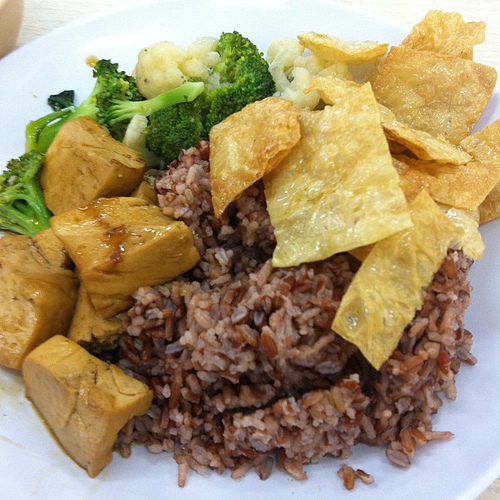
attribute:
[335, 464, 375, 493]
rice — brown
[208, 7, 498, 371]
food — crispy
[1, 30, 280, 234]
broccoli — green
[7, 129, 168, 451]
meat — white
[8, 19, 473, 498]
plate — white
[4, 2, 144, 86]
table — white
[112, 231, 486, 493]
rice — brown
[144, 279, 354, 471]
rice — brown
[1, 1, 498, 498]
dish — white, flat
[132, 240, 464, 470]
rice — brown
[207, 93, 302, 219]
chip — crispy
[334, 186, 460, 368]
chip — crispy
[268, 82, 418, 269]
chip — crispy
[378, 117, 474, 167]
chip — crispy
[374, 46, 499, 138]
chip — crispy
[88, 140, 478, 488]
rice — brown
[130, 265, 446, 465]
rice — brown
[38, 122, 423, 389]
tortillas — fried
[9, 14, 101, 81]
dish — white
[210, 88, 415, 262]
food — crispy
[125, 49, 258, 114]
food — white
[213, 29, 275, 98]
cauliflower — steamed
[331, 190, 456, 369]
tortilla chip — crisp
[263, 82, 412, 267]
tortilla chip — crisp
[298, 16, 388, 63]
tortilla chip — crisp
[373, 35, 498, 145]
tortilla chip — crisp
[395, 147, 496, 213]
tortilla chip — crisp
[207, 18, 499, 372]
chips — brown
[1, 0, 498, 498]
plate — white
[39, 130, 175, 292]
meat — square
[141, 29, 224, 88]
cauliflower — white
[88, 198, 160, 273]
sauce — brown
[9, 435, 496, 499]
plate — white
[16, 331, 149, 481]
meat — square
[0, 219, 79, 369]
meat — square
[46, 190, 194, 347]
meat — square